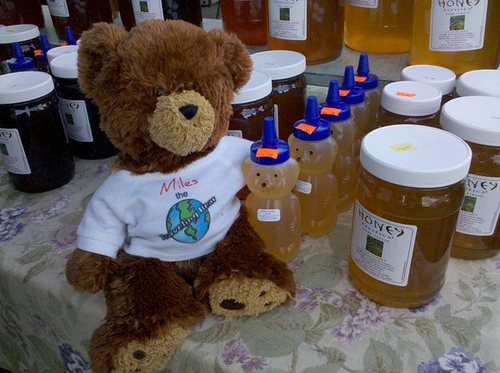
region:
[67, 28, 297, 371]
brown teddy bear with white shirt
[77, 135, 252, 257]
white t-shirt on bear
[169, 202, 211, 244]
globe on the t-shirt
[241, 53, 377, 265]
5 bottles of honey with shaped like a bear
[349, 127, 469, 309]
jar of honey on the right with yellow price tag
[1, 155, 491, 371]
green table cloth with purple flowers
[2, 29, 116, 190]
very dark colored honey behind the bear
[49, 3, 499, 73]
jars of honey on the shelf above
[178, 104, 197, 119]
the bear's black nose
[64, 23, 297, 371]
teddy bear with arm around a bottle of honey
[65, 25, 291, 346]
a brown teddy bear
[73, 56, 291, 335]
a brown teddy bear wearing a white shirt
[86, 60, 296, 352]
a teddy bear wearing a white shirt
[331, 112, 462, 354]
a bottle of honey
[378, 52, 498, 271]
bottles of honey on a table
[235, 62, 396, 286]
bear shaped bottles of honey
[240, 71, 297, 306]
a bear shaped bottle of honey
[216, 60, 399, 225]
bear shaped bottles of honey on a table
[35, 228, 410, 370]
a flowered table cloth on a table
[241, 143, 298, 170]
a orange sticker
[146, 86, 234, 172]
nose of the doll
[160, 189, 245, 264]
a small logo in shirt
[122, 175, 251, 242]
a globe logo in shirt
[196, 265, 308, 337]
legs of the doll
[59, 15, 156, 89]
ears of the doll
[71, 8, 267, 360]
a cute teddy bear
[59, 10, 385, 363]
a hot bear in table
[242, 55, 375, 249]
a series of bottles like teddy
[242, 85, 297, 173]
cap of the bottle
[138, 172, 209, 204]
red text on shirt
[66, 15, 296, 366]
a teddy bear holding a bottle of honey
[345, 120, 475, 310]
a fresh jar of honey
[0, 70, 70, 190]
a fresh jar of honey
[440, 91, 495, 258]
a fresh jar of honey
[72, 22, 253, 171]
the head of a teddy bear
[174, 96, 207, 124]
the nose of a teddy bear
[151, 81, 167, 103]
the eye of a teddy bear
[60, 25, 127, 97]
the ear of a teddy bear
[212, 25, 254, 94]
the ear of a teddy bear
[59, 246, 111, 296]
the paw of a teddy bear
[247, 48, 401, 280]
these plastic bottles are modeled into bears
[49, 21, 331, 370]
a brown teddy bear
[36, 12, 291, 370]
the bear is wearing a white tee shirt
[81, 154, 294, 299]
the shirt says "Miles the Traveling Bear"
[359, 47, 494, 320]
jars of honey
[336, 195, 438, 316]
a white label on a jar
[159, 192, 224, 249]
a cartoon drawing of the earth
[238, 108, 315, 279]
the bottles have blue lids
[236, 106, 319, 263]
the lids have a squeeze nozzle top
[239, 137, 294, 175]
an orange sticker price tag